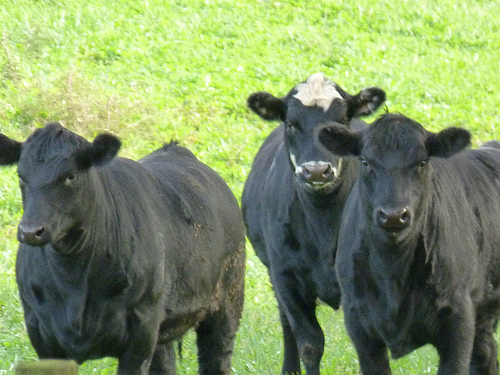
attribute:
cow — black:
[23, 105, 241, 372]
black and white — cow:
[289, 73, 350, 139]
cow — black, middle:
[251, 69, 342, 270]